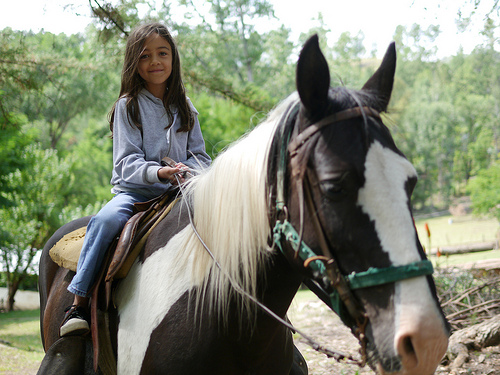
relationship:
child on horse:
[59, 22, 212, 337] [37, 32, 452, 375]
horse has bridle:
[37, 32, 452, 375] [280, 212, 439, 328]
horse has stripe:
[37, 32, 452, 375] [357, 140, 451, 355]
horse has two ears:
[37, 32, 452, 375] [248, 15, 474, 117]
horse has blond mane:
[37, 32, 452, 375] [169, 90, 300, 340]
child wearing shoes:
[59, 22, 212, 337] [59, 299, 92, 339]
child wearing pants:
[59, 22, 212, 337] [59, 184, 173, 305]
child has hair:
[59, 22, 212, 337] [106, 22, 192, 133]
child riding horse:
[59, 22, 212, 337] [45, 106, 460, 372]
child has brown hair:
[121, 31, 216, 178] [106, 22, 194, 139]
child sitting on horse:
[59, 22, 212, 337] [37, 32, 452, 375]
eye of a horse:
[317, 172, 342, 205] [37, 32, 452, 375]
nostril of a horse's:
[395, 334, 421, 369] [24, 31, 450, 373]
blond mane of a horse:
[169, 90, 300, 340] [37, 32, 452, 375]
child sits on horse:
[59, 22, 212, 337] [37, 32, 452, 375]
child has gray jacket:
[59, 22, 212, 337] [110, 88, 212, 199]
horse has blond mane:
[41, 26, 496, 373] [183, 129, 287, 313]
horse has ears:
[37, 32, 452, 375] [279, 31, 341, 118]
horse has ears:
[37, 32, 452, 375] [356, 32, 405, 117]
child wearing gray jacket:
[59, 22, 212, 337] [110, 88, 212, 199]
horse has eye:
[37, 32, 452, 375] [318, 182, 344, 200]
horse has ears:
[37, 32, 452, 375] [296, 33, 331, 107]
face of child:
[134, 34, 174, 83] [59, 22, 212, 337]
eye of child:
[155, 47, 169, 61] [59, 22, 212, 337]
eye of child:
[141, 52, 153, 60] [59, 22, 212, 337]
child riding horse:
[59, 22, 212, 337] [37, 32, 452, 375]